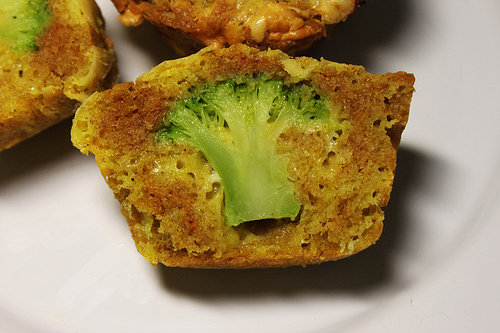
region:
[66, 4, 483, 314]
a muffin cut in half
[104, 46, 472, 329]
a muffin on a plate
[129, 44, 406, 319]
a brea on a plate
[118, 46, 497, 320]
a muffin on a white plate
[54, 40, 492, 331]
a bread on a white plate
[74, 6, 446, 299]
brocolli in a muffin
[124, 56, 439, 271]
green brocolli in a muffin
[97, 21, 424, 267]
brocolli in a bread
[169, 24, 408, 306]
green brocolli in a bread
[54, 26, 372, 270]
a slice of bread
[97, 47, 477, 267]
a delicious tasty food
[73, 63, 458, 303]
a hot looking food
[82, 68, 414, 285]
a tasty looking food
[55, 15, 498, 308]
a sweet looking food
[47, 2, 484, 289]
a delicious looking food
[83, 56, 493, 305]
a superb looking food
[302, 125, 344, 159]
holes in the food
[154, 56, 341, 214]
a green tree in food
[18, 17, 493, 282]
a piece of the food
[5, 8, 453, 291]
a group of food items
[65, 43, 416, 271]
A pastry with half a piece of broccoli in it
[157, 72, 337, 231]
A piece of green broccoli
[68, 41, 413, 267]
A brown colored pastry with a green vegitable in it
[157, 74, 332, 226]
Half of a broccoli floret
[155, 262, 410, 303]
A shadow on a plate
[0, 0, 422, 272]
A bunch of pastries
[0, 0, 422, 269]
A bunch of pastries, cut in half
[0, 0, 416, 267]
A bunch of pastries, cut in half, with green broccoli in them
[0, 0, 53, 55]
Green broccoli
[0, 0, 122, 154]
A pastry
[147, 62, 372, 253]
Broccoli inside a cupcake.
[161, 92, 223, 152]
Floret of a broccoli stem.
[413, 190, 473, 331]
White table made of wood.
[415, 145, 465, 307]
Shadow of cupcake on table.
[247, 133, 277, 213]
Inside of broccoli stem.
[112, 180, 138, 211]
Hole inside a cupcake.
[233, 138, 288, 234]
The white of broccoli.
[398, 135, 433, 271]
Black shadow on a white table.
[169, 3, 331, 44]
Crust of a cupcake.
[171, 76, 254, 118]
Green top of broccoli.